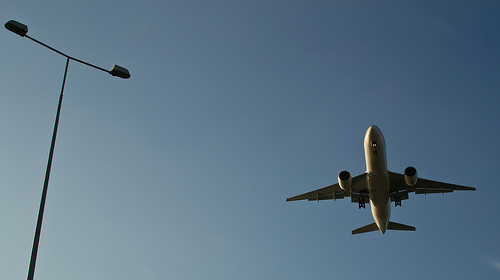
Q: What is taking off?
A: Plane.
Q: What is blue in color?
A: The sky.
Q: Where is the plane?
A: In the sky.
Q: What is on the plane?
A: Wings.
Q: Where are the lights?
A: Next to the plane.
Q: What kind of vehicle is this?
A: Plane.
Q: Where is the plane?
A: Sky.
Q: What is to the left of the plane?
A: Street lamps.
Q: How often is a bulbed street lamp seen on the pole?
A: Twice.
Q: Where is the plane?
A: Sky.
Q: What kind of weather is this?
A: Sunny and clear.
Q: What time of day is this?
A: Daylight hours.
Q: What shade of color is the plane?
A: White.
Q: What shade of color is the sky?
A: Blue.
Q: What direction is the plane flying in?
A: Left.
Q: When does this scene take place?
A: Daytime.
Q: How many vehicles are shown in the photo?
A: One.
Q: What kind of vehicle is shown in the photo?
A: Airplane.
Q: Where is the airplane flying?
A: Sky.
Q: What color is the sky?
A: Blue.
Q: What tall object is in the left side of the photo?
A: Street lamp.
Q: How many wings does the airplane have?
A: Two.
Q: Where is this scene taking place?
A: In the air.